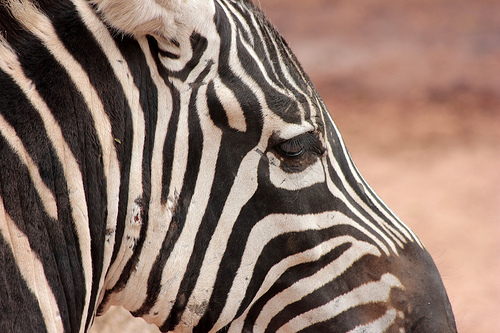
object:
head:
[91, 1, 458, 333]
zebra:
[0, 0, 457, 333]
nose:
[396, 242, 459, 331]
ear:
[95, 2, 218, 37]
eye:
[274, 133, 310, 157]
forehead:
[212, 0, 332, 133]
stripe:
[212, 1, 265, 133]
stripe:
[220, 1, 253, 47]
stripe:
[329, 158, 373, 223]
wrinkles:
[71, 212, 128, 330]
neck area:
[6, 0, 160, 333]